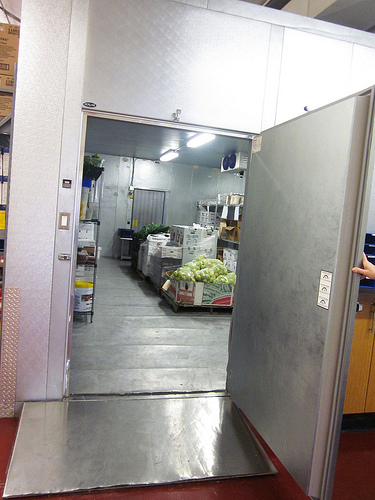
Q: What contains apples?
A: The box contains apples.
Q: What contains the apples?
A: The box contains apples.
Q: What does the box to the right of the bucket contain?
A: The box contains apples.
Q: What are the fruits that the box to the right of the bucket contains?
A: The fruits are apples.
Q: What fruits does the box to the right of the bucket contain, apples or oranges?
A: The box contains apples.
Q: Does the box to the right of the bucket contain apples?
A: Yes, the box contains apples.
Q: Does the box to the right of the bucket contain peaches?
A: No, the box contains apples.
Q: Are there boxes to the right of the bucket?
A: Yes, there is a box to the right of the bucket.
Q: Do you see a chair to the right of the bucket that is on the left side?
A: No, there is a box to the right of the bucket.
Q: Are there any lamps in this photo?
A: No, there are no lamps.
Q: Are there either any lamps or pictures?
A: No, there are no lamps or pictures.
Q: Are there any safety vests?
A: No, there are no safety vests.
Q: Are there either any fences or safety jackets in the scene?
A: No, there are no safety jackets or fences.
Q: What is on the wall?
A: The fan is on the wall.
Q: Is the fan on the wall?
A: Yes, the fan is on the wall.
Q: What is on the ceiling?
A: The fan is on the ceiling.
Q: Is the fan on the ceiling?
A: Yes, the fan is on the ceiling.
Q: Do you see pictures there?
A: No, there are no pictures.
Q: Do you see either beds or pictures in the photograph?
A: No, there are no pictures or beds.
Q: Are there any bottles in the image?
A: No, there are no bottles.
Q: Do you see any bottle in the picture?
A: No, there are no bottles.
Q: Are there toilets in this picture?
A: No, there are no toilets.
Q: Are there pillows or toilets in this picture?
A: No, there are no toilets or pillows.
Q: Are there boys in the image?
A: No, there are no boys.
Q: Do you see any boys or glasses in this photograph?
A: No, there are no boys or glasses.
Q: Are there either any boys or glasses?
A: No, there are no boys or glasses.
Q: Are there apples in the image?
A: Yes, there are apples.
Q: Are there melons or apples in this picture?
A: Yes, there are apples.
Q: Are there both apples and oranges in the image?
A: No, there are apples but no oranges.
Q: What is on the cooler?
A: The apples are on the cooler.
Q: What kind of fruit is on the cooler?
A: The fruits are apples.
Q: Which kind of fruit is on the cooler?
A: The fruits are apples.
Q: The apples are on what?
A: The apples are on the cooler.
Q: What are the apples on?
A: The apples are on the cooler.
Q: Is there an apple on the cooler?
A: Yes, there are apples on the cooler.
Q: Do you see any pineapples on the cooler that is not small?
A: No, there are apples on the cooler.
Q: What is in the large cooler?
A: The apples are in the cooler.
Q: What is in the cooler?
A: The apples are in the cooler.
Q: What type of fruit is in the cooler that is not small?
A: The fruits are apples.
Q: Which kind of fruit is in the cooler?
A: The fruits are apples.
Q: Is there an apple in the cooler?
A: Yes, there are apples in the cooler.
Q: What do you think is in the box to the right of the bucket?
A: The apples are in the box.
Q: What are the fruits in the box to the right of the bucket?
A: The fruits are apples.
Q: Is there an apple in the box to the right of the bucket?
A: Yes, there are apples in the box.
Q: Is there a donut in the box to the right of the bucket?
A: No, there are apples in the box.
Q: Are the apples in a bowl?
A: No, the apples are in the box.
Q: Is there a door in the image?
A: Yes, there is a door.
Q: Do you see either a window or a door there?
A: Yes, there is a door.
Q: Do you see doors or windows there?
A: Yes, there is a door.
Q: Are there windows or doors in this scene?
A: Yes, there is a door.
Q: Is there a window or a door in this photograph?
A: Yes, there is a door.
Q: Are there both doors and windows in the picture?
A: No, there is a door but no windows.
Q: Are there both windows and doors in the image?
A: No, there is a door but no windows.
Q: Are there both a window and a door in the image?
A: No, there is a door but no windows.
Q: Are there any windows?
A: No, there are no windows.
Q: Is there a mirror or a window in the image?
A: No, there are no windows or mirrors.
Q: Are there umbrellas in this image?
A: No, there are no umbrellas.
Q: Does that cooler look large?
A: Yes, the cooler is large.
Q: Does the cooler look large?
A: Yes, the cooler is large.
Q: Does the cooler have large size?
A: Yes, the cooler is large.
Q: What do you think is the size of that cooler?
A: The cooler is large.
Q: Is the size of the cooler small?
A: No, the cooler is large.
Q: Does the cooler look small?
A: No, the cooler is large.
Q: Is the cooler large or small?
A: The cooler is large.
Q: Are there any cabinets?
A: Yes, there is a cabinet.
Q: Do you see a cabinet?
A: Yes, there is a cabinet.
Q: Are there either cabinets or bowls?
A: Yes, there is a cabinet.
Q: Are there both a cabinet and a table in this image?
A: No, there is a cabinet but no tables.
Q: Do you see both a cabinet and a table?
A: No, there is a cabinet but no tables.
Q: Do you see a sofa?
A: No, there are no sofas.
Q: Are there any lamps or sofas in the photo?
A: No, there are no sofas or lamps.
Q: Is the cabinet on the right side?
A: Yes, the cabinet is on the right of the image.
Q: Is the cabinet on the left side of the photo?
A: No, the cabinet is on the right of the image.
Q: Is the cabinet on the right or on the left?
A: The cabinet is on the right of the image.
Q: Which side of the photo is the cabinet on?
A: The cabinet is on the right of the image.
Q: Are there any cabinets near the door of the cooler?
A: Yes, there is a cabinet near the door.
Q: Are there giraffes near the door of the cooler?
A: No, there is a cabinet near the door.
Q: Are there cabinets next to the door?
A: Yes, there is a cabinet next to the door.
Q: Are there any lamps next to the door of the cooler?
A: No, there is a cabinet next to the door.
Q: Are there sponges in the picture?
A: No, there are no sponges.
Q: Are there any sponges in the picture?
A: No, there are no sponges.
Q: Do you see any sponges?
A: No, there are no sponges.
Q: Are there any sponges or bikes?
A: No, there are no sponges or bikes.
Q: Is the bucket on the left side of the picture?
A: Yes, the bucket is on the left of the image.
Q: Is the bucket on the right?
A: No, the bucket is on the left of the image.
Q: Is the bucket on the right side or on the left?
A: The bucket is on the left of the image.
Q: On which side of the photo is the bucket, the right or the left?
A: The bucket is on the left of the image.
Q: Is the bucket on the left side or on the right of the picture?
A: The bucket is on the left of the image.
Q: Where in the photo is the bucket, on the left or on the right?
A: The bucket is on the left of the image.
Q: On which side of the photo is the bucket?
A: The bucket is on the left of the image.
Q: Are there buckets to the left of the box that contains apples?
A: Yes, there is a bucket to the left of the box.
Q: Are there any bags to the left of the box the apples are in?
A: No, there is a bucket to the left of the box.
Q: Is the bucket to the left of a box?
A: Yes, the bucket is to the left of a box.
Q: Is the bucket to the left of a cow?
A: No, the bucket is to the left of a box.